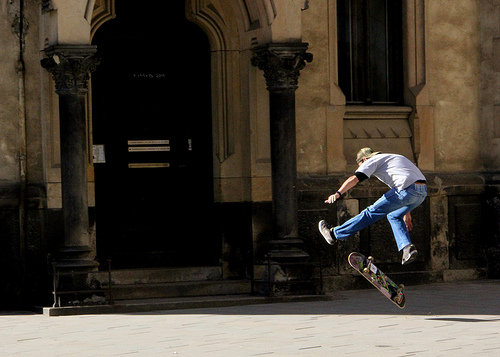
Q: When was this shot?
A: Daytime.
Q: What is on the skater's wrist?
A: Watch.